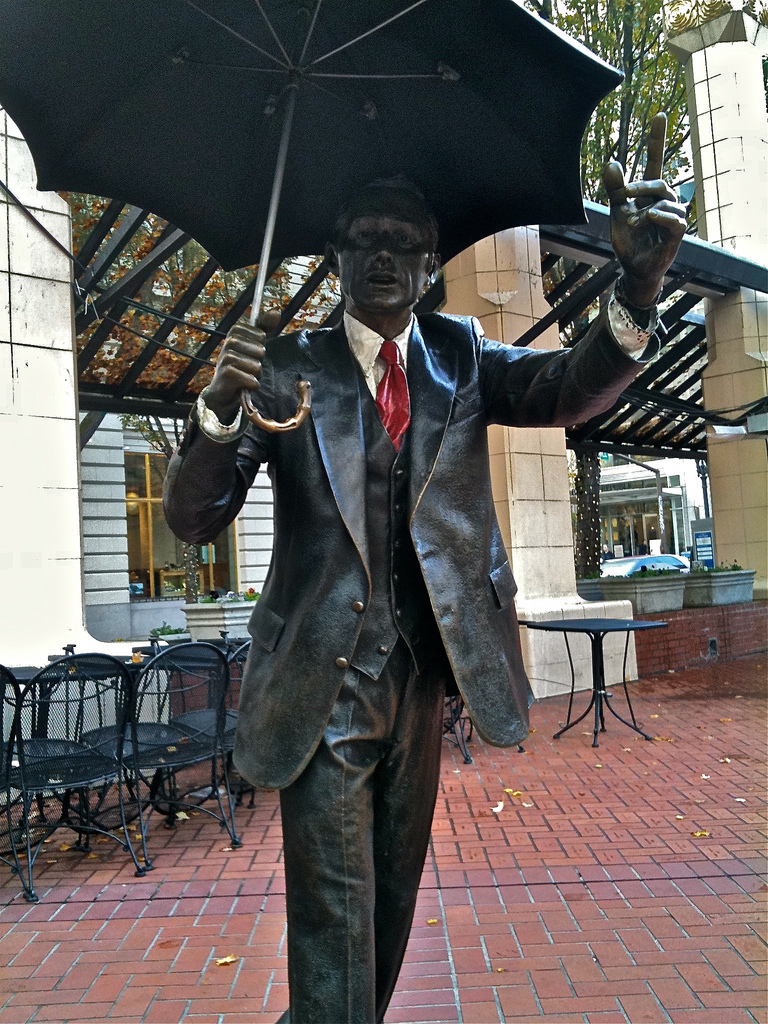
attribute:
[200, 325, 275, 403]
hand —  statue's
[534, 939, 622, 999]
brick —  ground ,  red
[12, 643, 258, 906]
blackchair —  black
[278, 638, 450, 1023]
leg —  man's,  below torso 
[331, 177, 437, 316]
head —  man's, with facial area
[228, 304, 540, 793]
shirt —  man's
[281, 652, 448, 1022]
pants —  man's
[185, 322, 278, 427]
hand —  man's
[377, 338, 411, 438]
tie —  red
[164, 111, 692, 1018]
man —  statue,  in suit,  with umbrella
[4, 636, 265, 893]
chairs —  black,  metal,  mesh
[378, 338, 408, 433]
tie —  red , for neck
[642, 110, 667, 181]
index finger — raised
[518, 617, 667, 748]
table —  black 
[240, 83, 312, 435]
handle — curved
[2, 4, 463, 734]
building — grey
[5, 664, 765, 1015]
sidewalk —  red,  brick,  area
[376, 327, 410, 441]
tie — red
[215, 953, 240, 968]
leaf — brown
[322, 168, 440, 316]
head —  man's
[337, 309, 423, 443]
dress shirt —  white